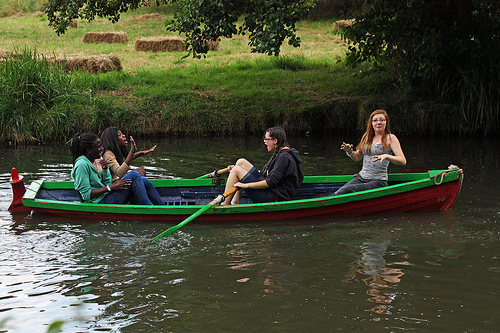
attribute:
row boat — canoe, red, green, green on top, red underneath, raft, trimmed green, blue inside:
[7, 166, 465, 224]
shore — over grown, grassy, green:
[4, 63, 498, 141]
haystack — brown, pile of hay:
[40, 56, 119, 74]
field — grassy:
[0, 0, 394, 72]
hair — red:
[360, 109, 392, 152]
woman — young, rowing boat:
[219, 126, 302, 202]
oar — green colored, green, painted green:
[152, 185, 240, 242]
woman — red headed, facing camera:
[333, 107, 408, 197]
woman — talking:
[100, 126, 171, 205]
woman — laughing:
[71, 134, 149, 203]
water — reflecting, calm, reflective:
[0, 133, 500, 332]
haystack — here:
[80, 32, 128, 45]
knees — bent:
[225, 157, 254, 180]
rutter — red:
[8, 166, 26, 215]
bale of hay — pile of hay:
[134, 38, 189, 55]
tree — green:
[42, 0, 499, 96]